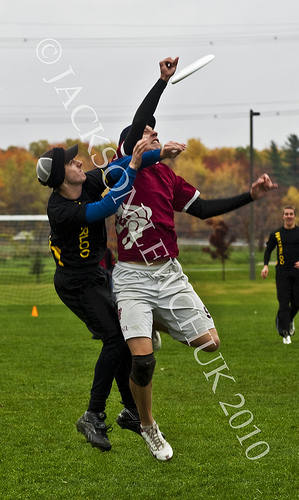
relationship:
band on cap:
[47, 140, 66, 198] [35, 136, 91, 192]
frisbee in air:
[162, 40, 263, 109] [116, 9, 279, 128]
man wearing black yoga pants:
[35, 137, 156, 451] [49, 262, 129, 436]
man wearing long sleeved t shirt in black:
[108, 53, 278, 463] [202, 202, 216, 216]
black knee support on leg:
[103, 350, 124, 367] [114, 259, 214, 457]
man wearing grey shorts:
[108, 85, 236, 467] [108, 258, 218, 344]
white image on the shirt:
[140, 220, 143, 224] [105, 153, 203, 268]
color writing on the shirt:
[45, 232, 66, 269] [42, 186, 113, 266]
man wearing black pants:
[38, 137, 135, 432] [45, 265, 126, 341]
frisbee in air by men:
[169, 51, 215, 89] [23, 72, 261, 462]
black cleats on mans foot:
[98, 406, 108, 426] [64, 399, 122, 464]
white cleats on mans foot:
[163, 447, 174, 453] [125, 329, 187, 471]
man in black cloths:
[262, 198, 296, 339] [259, 228, 297, 339]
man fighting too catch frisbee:
[35, 137, 156, 451] [165, 51, 230, 88]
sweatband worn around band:
[45, 146, 66, 188] [35, 143, 77, 191]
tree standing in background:
[201, 218, 239, 280] [1, 94, 289, 290]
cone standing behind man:
[29, 304, 39, 317] [35, 137, 156, 451]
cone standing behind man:
[29, 304, 39, 317] [108, 53, 278, 463]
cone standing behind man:
[29, 304, 39, 317] [262, 198, 298, 347]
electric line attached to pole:
[1, 113, 249, 118] [248, 108, 255, 281]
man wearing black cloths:
[262, 198, 298, 347] [262, 226, 299, 337]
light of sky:
[16, 35, 278, 132] [7, 11, 297, 149]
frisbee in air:
[169, 51, 215, 89] [1, 1, 297, 152]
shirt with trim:
[105, 153, 203, 268] [180, 185, 201, 211]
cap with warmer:
[34, 144, 76, 191] [50, 156, 63, 213]